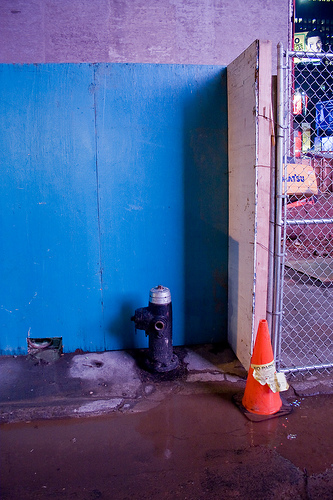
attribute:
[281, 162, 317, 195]
construction vehicle — yellow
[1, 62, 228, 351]
blue wall — bright blue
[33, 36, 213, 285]
wall — blue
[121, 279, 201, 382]
hydrant — blue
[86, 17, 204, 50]
wall — blue, gray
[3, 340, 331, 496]
floor — wet, brown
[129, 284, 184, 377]
fire hydrant — navy blue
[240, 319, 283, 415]
safety cone — orange, plastic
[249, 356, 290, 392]
paper — torn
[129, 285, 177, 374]
hydrant — navy blue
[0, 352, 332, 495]
cement pavement — wet, brown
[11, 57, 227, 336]
wall — blue, gray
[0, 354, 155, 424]
puddle — dirty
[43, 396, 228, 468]
pavement — wet, brown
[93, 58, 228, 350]
plywood — blue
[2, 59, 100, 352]
plywood — blue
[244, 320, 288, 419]
cone — orange